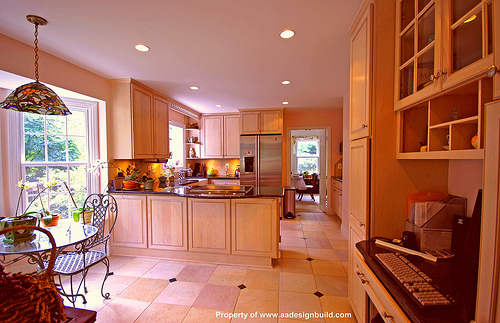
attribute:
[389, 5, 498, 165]
cabinets — wooden, light colored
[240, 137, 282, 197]
refrigerator — stainless steel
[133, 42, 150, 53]
lighting — recessed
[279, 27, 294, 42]
lighting — recessed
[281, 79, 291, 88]
lighting — recessed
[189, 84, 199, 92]
lighting — recessed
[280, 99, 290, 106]
lighting — recessed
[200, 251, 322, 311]
tile — tan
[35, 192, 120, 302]
chair — iron, wrought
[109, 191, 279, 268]
cabinet — light brown, wooden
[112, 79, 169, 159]
cabinet — wooden, light brown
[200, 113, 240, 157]
cabinet — wooden, light brown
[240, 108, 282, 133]
cabinet — wooden, light brown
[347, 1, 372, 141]
cabinet — wooden, light brown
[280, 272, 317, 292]
tile — tan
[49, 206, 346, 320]
tile floor — tan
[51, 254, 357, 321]
tiles — large, different colors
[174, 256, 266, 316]
tile — tan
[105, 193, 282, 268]
kitchen cabinets — wooden 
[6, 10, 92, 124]
lamp — stain glass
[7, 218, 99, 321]
table — round, glass, dining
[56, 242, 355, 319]
tiles — white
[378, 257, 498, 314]
keyboard — old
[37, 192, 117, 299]
metal chair — metallic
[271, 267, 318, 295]
tile — tan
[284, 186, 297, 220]
trash can — stainless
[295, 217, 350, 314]
floor — geometric pattern, tile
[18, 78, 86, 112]
light — hanging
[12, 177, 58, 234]
flowers — yellow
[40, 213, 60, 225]
pot — green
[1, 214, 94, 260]
table — glass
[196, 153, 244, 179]
backsplash — lit up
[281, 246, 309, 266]
tile — tan